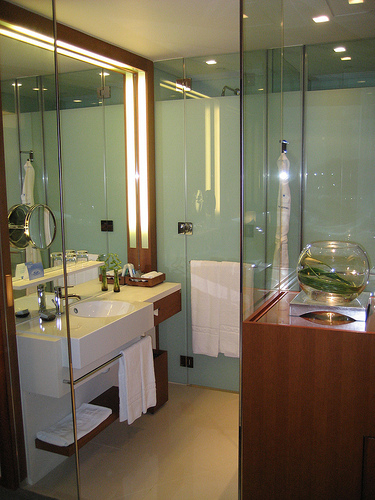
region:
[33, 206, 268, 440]
This is a bathroom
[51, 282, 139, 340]
This is a photo of a sink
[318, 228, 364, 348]
This is a fishbowl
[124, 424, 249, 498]
The floor is laquered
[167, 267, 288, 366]
These are white towels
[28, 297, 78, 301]
This is a faucet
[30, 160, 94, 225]
This is a mirror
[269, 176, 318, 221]
This is a shower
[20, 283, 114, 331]
The faucet is metal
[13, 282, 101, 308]
The faucet is silver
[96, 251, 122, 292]
two vases are on the counter top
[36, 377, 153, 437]
shelf is under the sink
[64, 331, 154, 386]
towel bar is under the sink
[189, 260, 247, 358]
towels are hanging from bar on wall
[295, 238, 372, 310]
fish bowl has water and foliage in it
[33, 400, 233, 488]
floor consist of tan ceramic tiles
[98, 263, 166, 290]
toiletries are in wooden box on counter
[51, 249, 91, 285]
water glasses are on counter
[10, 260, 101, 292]
white shelf is adhered to the mirror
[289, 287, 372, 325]
base of fish bowl is silver in color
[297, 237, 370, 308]
fish bowl on dresser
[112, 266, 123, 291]
glass vase on sink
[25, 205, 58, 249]
mirror on the mirror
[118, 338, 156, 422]
towel hanging on rack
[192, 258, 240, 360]
towel hanging on wall rack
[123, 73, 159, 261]
light fixture on the wall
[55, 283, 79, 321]
faucet on the sink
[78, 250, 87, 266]
glass cup on shelf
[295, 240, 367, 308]
water bowl on dresser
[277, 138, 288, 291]
towel on the hook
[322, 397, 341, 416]
part of a table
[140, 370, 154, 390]
part of a towel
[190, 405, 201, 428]
part of the surface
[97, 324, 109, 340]
part of a sink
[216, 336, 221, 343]
part of a towel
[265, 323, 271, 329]
edge of a table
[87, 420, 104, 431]
part of a towel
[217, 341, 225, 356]
part of a towel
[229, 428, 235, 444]
part of the floor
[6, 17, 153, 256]
The light is on.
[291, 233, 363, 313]
The bowl is clear.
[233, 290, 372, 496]
The dresser is brown.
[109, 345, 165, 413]
The towel is white.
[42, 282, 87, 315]
The faucet is silver.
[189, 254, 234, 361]
The towels are white.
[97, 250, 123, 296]
The plant is green.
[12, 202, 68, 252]
The mirror is circular.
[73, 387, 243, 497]
The floor is tan.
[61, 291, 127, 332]
The sink is white.